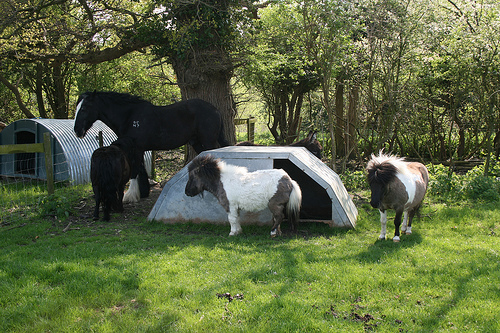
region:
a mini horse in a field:
[361, 143, 440, 247]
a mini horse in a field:
[182, 159, 308, 241]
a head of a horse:
[69, 84, 104, 137]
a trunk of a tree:
[324, 87, 346, 158]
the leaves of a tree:
[268, 25, 298, 66]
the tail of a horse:
[289, 177, 307, 217]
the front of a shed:
[2, 114, 77, 192]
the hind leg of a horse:
[266, 197, 286, 242]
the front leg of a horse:
[221, 200, 242, 244]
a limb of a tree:
[101, 17, 175, 54]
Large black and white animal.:
[359, 140, 425, 220]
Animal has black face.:
[370, 168, 395, 227]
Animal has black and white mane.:
[359, 145, 392, 198]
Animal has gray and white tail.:
[271, 197, 319, 225]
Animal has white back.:
[218, 162, 280, 205]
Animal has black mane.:
[188, 155, 219, 190]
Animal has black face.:
[178, 176, 205, 205]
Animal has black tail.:
[90, 146, 128, 191]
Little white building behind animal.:
[200, 142, 341, 218]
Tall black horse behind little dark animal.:
[66, 100, 231, 151]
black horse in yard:
[83, 89, 235, 164]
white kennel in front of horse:
[168, 131, 365, 252]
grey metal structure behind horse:
[0, 101, 105, 188]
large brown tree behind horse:
[132, 12, 244, 184]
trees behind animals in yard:
[263, 15, 496, 197]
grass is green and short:
[9, 215, 484, 331]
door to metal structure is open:
[13, 129, 34, 179]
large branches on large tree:
[38, 3, 263, 138]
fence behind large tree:
[218, 110, 275, 159]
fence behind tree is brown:
[232, 99, 264, 151]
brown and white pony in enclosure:
[178, 153, 303, 244]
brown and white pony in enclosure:
[360, 152, 432, 248]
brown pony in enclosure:
[82, 147, 127, 222]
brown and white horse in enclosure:
[73, 84, 217, 131]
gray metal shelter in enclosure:
[11, 121, 71, 188]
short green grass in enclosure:
[18, 221, 207, 324]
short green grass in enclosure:
[206, 237, 485, 331]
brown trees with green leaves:
[7, 8, 221, 83]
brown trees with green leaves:
[230, 5, 399, 128]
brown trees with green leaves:
[377, 12, 484, 148]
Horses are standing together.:
[45, 40, 460, 282]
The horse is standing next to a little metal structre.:
[130, 135, 368, 255]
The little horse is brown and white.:
[340, 141, 438, 247]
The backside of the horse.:
[76, 140, 138, 220]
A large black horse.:
[50, 80, 230, 190]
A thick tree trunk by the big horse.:
[145, 1, 255, 146]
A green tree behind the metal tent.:
[240, 6, 330, 148]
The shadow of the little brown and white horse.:
[360, 228, 423, 268]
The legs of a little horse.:
[210, 205, 293, 241]